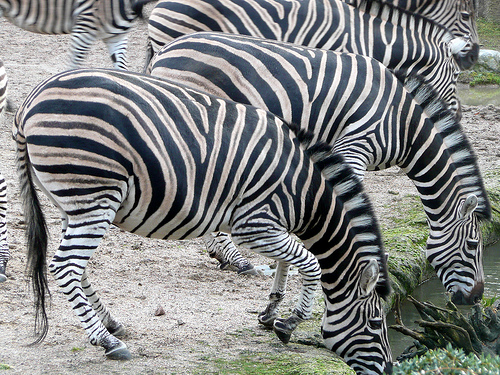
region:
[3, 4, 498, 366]
group of animals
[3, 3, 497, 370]
some zebras drinking water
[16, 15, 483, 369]
a scene outside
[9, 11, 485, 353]
a photo of a field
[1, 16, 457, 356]
some gray dirt on the ground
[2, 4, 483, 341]
a scene during the day time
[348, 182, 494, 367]
a river spot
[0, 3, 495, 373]
a group of animals drinking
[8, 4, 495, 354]
some animals that are thristy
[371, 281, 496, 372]
a patch of small batches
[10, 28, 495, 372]
Zebras drinking water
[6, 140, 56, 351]
Zebra tail with black hair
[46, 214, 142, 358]
Zebra's bent hind legs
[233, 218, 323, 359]
Zebra's bent frong legs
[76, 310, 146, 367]
Zebra hoofs on the ground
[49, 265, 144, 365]
Two Zebra hoofs on dirt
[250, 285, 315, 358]
Two front zebra hoofs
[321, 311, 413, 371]
Zebra's head in the ground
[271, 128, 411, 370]
Zebra's next bent downward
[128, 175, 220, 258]
The belly of a zebra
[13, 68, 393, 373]
Black and white zebra drinking water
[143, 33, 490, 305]
Black and white zebra drinking water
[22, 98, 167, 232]
Black stripe on zebra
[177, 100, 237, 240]
Black stripe on zebra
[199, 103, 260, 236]
Black stripe on zebra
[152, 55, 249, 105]
Black stripe on zebra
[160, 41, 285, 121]
Black stripe on zebra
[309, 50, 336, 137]
Black stripe on zebra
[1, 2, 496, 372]
these are zebraas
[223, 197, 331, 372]
the zebra's legs are curled forward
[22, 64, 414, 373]
this zebra is drinking water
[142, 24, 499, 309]
a zebra drinking water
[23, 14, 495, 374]
the zebras are drinking water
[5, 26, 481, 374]
the zebras have stripes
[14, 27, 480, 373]
the zebras are black, white and brown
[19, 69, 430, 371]
the zebras has black stripes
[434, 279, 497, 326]
the zebra's mouth is in the water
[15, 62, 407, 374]
the zebra has its head down to drink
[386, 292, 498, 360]
Dead tree roots near water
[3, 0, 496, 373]
Group of zebras next to water hole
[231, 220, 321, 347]
Zebra's legs bent at the knee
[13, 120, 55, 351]
Zebra's long tail touching the ground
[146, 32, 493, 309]
Zebra drinking water from water hole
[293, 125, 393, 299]
Striped mane on zebra's neck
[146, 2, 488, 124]
Zebras walking toward the water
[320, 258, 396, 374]
Zebra's head near the ground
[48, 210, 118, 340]
Short stripes on zebra's rear legs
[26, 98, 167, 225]
Large black stripe on zebra's rear